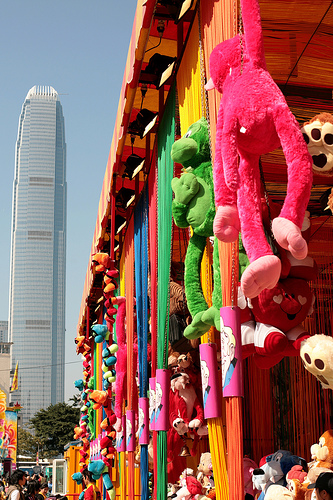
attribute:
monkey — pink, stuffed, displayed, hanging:
[203, 0, 315, 299]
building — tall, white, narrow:
[7, 85, 67, 436]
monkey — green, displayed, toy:
[169, 117, 252, 340]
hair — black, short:
[9, 469, 27, 484]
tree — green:
[28, 401, 82, 458]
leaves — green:
[26, 401, 81, 456]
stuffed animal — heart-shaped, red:
[238, 276, 319, 369]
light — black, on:
[127, 107, 160, 141]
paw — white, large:
[298, 110, 332, 172]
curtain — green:
[156, 79, 179, 500]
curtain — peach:
[197, 1, 244, 500]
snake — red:
[91, 252, 120, 331]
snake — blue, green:
[91, 323, 120, 391]